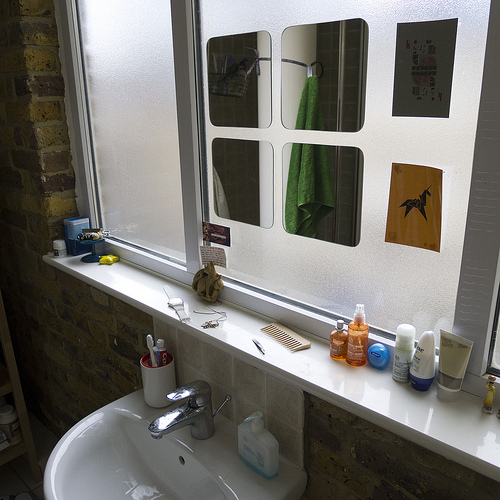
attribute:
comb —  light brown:
[257, 320, 310, 352]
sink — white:
[38, 380, 310, 499]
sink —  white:
[33, 410, 313, 498]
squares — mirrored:
[234, 50, 380, 242]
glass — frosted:
[220, 0, 274, 32]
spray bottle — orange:
[342, 301, 370, 364]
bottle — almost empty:
[236, 412, 281, 481]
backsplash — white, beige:
[151, 313, 312, 465]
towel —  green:
[285, 74, 342, 235]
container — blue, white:
[228, 407, 285, 484]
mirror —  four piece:
[205, 17, 368, 247]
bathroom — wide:
[2, 0, 497, 497]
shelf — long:
[27, 232, 497, 484]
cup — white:
[140, 353, 178, 405]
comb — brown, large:
[259, 322, 313, 352]